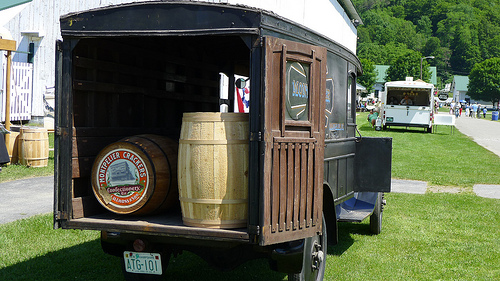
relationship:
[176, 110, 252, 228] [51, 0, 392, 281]
barrel in back of car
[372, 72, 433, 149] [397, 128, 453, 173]
truck in grass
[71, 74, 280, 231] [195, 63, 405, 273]
door on truck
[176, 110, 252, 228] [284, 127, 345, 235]
barrel in truck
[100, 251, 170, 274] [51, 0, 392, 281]
license plate on car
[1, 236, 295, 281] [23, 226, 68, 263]
shadow on grass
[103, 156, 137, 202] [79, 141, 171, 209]
label on barrel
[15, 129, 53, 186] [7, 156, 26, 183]
barrel on grass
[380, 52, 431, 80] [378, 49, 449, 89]
leaves on trees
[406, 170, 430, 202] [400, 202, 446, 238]
stone in grass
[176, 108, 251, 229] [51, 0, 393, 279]
barrel inside of car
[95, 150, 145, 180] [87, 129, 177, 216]
lettering on barrel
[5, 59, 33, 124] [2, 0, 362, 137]
fence next to barn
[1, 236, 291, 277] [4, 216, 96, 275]
shadow on ground